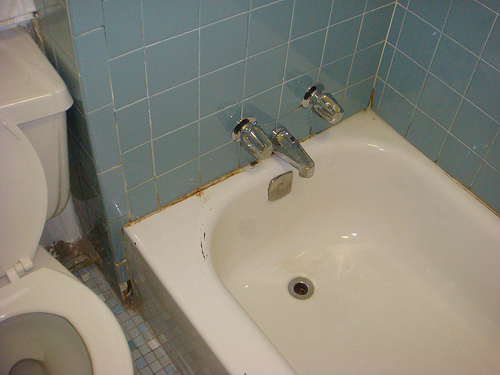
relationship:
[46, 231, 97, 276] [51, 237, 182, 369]
dirt on floor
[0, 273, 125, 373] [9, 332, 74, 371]
toilet bowl with water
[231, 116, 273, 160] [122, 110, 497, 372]
knob over bathtub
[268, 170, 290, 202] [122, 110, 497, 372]
patch on bathtub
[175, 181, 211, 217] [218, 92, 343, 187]
grout in shower